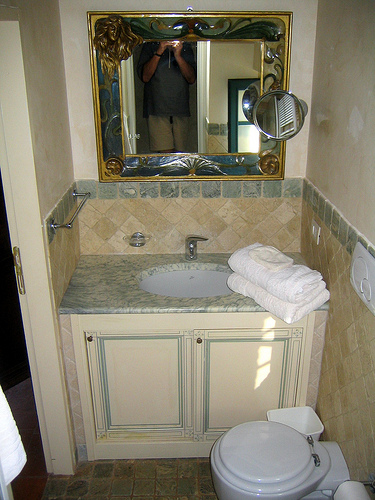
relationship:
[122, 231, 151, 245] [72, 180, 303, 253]
soap dish hanging on wall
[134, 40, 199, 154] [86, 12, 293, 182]
man reflected in mirror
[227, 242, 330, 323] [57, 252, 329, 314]
towels on counter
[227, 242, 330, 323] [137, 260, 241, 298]
towels near sink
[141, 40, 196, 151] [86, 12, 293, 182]
man reflected in mirror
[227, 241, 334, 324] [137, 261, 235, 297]
towel in sink